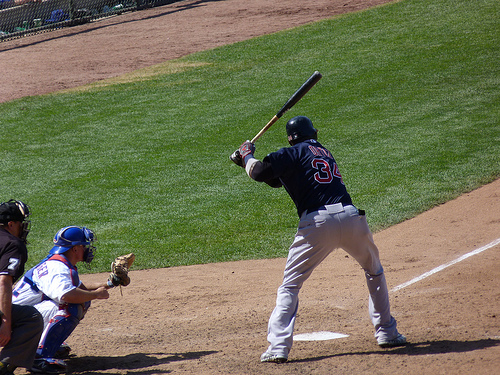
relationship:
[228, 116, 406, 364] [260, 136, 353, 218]
player wearing a jersey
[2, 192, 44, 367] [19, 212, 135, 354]
umpire behind catcher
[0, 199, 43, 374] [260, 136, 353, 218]
umpire wearing jersey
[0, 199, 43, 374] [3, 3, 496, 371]
umpire playing baseball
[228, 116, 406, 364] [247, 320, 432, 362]
player wearing shoes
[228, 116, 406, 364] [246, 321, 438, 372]
player wearing shoes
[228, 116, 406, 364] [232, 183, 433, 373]
player wearing white pants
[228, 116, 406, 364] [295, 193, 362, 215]
player wearing a belt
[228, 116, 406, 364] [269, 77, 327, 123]
player holding bat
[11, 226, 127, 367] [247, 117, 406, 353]
man squatting behind batter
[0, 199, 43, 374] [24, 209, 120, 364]
umpire behind catcher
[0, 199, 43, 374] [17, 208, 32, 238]
umpire wearing a face mask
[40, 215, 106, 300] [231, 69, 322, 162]
man swinging bat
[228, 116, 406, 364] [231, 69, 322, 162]
player swinging bat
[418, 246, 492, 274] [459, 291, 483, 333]
line on clay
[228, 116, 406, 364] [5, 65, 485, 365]
player playing baseball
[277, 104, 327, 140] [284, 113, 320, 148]
helmet on head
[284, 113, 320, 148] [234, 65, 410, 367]
head on batter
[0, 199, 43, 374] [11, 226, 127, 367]
umpire behind man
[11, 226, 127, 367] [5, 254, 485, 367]
man on mound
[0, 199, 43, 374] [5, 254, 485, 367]
umpire on mound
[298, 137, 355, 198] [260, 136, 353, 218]
number on jersey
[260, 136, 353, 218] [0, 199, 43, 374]
jersey on umpire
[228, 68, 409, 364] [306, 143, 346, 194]
player has number